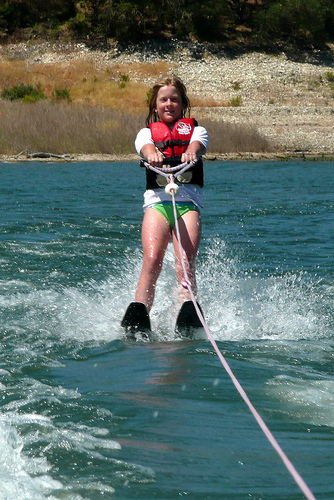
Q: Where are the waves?
A: In the water.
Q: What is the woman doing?
A: Water skiing.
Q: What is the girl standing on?
A: Water skis.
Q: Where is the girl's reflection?
A: In the water.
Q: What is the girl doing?
A: She is holding on a rope and water skiing.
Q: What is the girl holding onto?
A: A rope that is pulling her.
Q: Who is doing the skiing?
A: A smiling female water skier.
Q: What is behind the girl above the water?
A: A rocking hillside next to the lake.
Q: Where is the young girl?
A: She is on water skis on a body of water.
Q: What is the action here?
A: Its a young girl water skiing on a body of water.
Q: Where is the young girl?
A: She is on water skis on water.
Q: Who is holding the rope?
A: A young girl who is water skiing on a body of water.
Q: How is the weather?
A: Sunny and warm.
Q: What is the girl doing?
A: Water skiing.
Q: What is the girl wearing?
A: A life vest.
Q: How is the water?
A: Splashing.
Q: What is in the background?
A: Trees and rocks.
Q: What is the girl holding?
A: A black handle.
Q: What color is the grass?
A: Brown.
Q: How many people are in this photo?
A: One.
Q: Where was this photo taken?
A: On the water.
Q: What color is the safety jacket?
A: Red.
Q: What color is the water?
A: Blue.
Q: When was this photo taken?
A: Outside, during the daytime.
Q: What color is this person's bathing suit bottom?
A: Green.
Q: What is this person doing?
A: Water skiing.